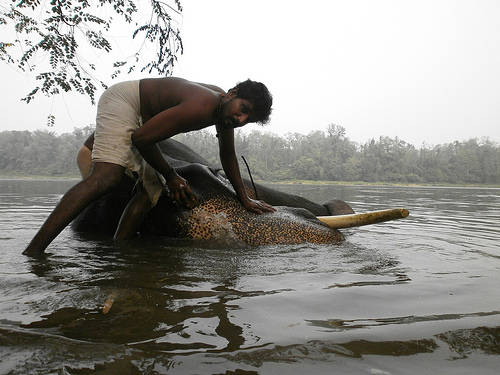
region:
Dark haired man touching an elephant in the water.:
[216, 77, 273, 130]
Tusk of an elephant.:
[311, 205, 409, 230]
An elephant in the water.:
[66, 126, 410, 249]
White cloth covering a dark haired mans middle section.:
[88, 75, 164, 206]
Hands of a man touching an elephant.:
[164, 175, 276, 216]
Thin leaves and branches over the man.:
[0, 1, 186, 126]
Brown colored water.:
[1, 176, 498, 373]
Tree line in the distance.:
[1, 121, 498, 187]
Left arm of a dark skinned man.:
[215, 123, 275, 215]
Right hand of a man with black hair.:
[165, 171, 198, 208]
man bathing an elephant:
[20, 76, 410, 259]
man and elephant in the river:
[21, 69, 463, 290]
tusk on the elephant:
[315, 206, 410, 227]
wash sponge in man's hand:
[165, 179, 202, 211]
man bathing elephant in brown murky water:
[18, 70, 416, 295]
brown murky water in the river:
[30, 290, 454, 356]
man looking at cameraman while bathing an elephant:
[22, 75, 272, 260]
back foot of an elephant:
[323, 199, 356, 215]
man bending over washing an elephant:
[22, 75, 273, 256]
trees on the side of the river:
[287, 122, 498, 183]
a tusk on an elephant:
[317, 200, 409, 226]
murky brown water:
[312, 200, 487, 362]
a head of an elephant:
[161, 175, 276, 250]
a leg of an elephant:
[221, 170, 381, 215]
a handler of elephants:
[22, 74, 281, 260]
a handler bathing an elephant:
[28, 67, 389, 258]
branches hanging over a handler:
[3, 2, 196, 99]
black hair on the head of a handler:
[232, 76, 278, 122]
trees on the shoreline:
[0, 118, 498, 184]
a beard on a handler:
[217, 93, 239, 130]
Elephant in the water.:
[71, 136, 416, 256]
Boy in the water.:
[20, 70, 282, 259]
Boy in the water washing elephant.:
[24, 71, 411, 266]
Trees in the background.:
[2, 121, 498, 191]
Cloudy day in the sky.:
[0, 1, 496, 138]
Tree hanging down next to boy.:
[0, 0, 197, 123]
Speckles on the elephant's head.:
[179, 198, 337, 248]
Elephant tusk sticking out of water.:
[315, 206, 420, 235]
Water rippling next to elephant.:
[5, 231, 498, 368]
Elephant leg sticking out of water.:
[211, 158, 357, 220]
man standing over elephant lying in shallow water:
[21, 72, 411, 278]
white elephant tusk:
[313, 207, 425, 227]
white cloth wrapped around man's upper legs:
[87, 80, 144, 177]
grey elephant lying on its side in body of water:
[71, 160, 412, 268]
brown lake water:
[270, 268, 425, 359]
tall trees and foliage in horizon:
[273, 132, 499, 187]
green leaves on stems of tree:
[1, 1, 191, 110]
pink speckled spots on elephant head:
[198, 200, 312, 247]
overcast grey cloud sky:
[325, 36, 463, 119]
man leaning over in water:
[6, 73, 291, 258]